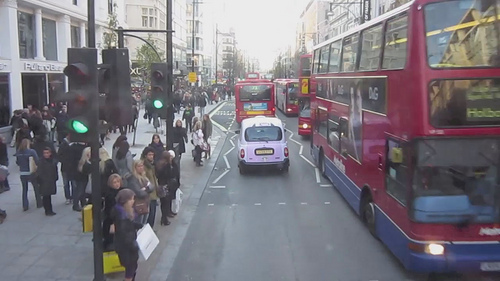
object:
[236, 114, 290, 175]
car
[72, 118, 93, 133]
stoplight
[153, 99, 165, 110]
stoplight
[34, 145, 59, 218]
pedestrian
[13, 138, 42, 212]
pedestrian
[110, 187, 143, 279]
pedestrian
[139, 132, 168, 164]
pedestrian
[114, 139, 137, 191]
pedestrian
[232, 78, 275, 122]
bus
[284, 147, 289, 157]
tail lights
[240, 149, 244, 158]
tail lights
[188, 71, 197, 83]
sign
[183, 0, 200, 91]
pole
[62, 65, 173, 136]
lights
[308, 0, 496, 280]
bus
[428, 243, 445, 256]
headlight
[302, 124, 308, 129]
headlight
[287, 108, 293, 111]
headlight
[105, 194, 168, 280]
woman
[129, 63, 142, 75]
letters "xt"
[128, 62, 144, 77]
sign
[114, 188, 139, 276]
people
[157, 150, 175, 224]
people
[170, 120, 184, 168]
people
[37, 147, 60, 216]
people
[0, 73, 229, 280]
people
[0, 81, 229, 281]
sidewalk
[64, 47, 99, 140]
signal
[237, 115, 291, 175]
vehicle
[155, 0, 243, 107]
building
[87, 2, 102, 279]
pole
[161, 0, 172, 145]
pole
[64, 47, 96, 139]
traffic light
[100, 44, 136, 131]
traffic light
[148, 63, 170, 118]
traffic light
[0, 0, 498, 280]
city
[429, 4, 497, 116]
buildings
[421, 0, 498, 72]
window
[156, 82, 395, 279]
street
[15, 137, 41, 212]
woman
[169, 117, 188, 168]
woman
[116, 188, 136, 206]
hair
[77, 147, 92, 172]
hair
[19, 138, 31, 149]
hair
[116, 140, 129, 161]
hair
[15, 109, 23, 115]
hair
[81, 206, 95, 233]
bag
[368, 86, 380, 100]
ad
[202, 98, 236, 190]
marking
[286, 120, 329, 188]
marking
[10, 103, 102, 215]
people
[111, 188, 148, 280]
person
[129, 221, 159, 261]
bag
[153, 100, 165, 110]
light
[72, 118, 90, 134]
light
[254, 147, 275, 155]
licence plate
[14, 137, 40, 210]
person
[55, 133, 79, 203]
person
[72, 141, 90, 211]
person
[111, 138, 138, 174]
person